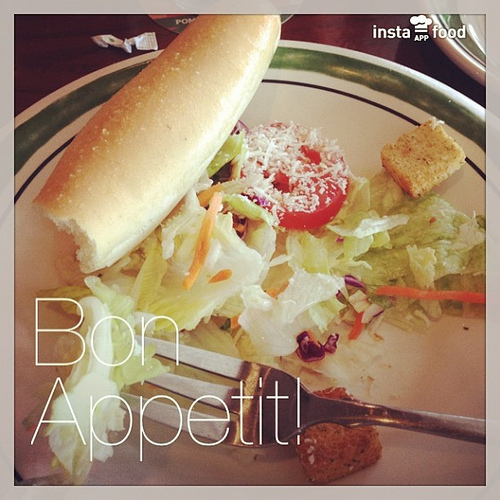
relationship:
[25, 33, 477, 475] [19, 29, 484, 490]
food on dish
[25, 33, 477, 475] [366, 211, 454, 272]
food contains lettuce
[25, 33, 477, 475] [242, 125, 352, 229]
food contains tomato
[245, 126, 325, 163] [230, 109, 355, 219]
chair has cheese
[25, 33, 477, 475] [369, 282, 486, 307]
food has carrots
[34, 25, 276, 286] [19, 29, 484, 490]
bread on dish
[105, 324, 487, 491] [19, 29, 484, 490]
fork on dish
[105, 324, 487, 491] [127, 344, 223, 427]
fork has prong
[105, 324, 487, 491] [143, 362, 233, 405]
fork has prong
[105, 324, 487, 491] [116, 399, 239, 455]
fork has prong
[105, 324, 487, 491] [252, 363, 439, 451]
fork has handle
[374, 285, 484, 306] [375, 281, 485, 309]
carrot piece in carrot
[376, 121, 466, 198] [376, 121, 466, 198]
crouton shaped like a crouton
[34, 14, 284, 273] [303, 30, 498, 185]
bread on plate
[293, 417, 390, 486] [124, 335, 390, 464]
crouton under fork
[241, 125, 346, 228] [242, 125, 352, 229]
cheese on tomato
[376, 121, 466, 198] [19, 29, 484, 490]
crouton on dish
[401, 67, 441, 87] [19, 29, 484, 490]
edge on dish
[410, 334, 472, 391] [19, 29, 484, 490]
part on dish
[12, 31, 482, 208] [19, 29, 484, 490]
green stripe on dish